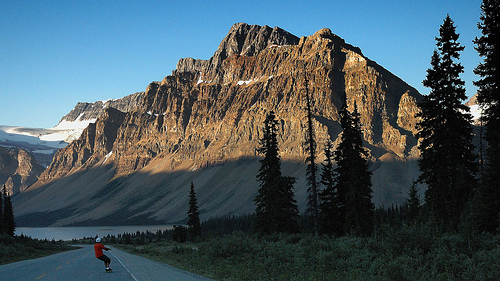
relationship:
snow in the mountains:
[10, 118, 82, 151] [77, 29, 381, 176]